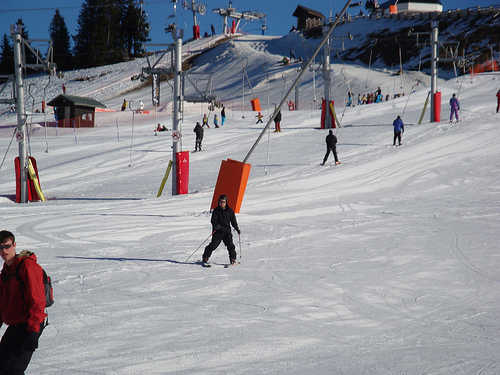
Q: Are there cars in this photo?
A: No, there are no cars.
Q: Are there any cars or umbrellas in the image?
A: No, there are no cars or umbrellas.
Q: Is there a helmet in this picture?
A: No, there are no helmets.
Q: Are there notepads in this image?
A: No, there are no notepads.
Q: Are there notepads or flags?
A: No, there are no notepads or flags.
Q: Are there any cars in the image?
A: No, there are no cars.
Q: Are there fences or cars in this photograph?
A: No, there are no cars or fences.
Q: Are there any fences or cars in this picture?
A: No, there are no fences or cars.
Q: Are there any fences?
A: No, there are no fences.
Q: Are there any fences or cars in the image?
A: No, there are no fences or cars.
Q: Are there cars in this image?
A: No, there are no cars.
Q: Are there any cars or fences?
A: No, there are no cars or fences.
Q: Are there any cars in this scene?
A: No, there are no cars.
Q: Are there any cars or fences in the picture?
A: No, there are no cars or fences.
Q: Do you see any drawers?
A: No, there are no drawers.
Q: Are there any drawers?
A: No, there are no drawers.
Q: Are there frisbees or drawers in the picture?
A: No, there are no drawers or frisbees.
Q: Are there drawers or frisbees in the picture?
A: No, there are no drawers or frisbees.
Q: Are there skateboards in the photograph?
A: No, there are no skateboards.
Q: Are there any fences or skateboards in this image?
A: No, there are no skateboards or fences.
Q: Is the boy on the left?
A: Yes, the boy is on the left of the image.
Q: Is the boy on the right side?
A: No, the boy is on the left of the image.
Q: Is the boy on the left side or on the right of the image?
A: The boy is on the left of the image.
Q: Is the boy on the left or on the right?
A: The boy is on the left of the image.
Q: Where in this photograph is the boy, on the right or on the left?
A: The boy is on the left of the image.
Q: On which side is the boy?
A: The boy is on the left of the image.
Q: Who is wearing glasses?
A: The boy is wearing glasses.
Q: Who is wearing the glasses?
A: The boy is wearing glasses.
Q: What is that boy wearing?
A: The boy is wearing glasses.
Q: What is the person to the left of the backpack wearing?
A: The boy is wearing glasses.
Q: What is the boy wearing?
A: The boy is wearing glasses.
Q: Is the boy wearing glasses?
A: Yes, the boy is wearing glasses.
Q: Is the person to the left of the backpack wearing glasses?
A: Yes, the boy is wearing glasses.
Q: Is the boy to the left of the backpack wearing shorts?
A: No, the boy is wearing glasses.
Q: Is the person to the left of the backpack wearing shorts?
A: No, the boy is wearing glasses.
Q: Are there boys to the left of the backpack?
A: Yes, there is a boy to the left of the backpack.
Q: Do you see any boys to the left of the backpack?
A: Yes, there is a boy to the left of the backpack.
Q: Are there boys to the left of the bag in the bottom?
A: Yes, there is a boy to the left of the backpack.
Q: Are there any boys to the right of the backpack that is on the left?
A: No, the boy is to the left of the backpack.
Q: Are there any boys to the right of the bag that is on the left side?
A: No, the boy is to the left of the backpack.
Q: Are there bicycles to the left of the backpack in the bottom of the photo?
A: No, there is a boy to the left of the backpack.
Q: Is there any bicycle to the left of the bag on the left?
A: No, there is a boy to the left of the backpack.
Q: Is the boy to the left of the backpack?
A: Yes, the boy is to the left of the backpack.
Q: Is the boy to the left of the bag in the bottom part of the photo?
A: Yes, the boy is to the left of the backpack.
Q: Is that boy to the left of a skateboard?
A: No, the boy is to the left of the backpack.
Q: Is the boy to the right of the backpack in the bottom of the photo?
A: No, the boy is to the left of the backpack.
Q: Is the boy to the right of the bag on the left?
A: No, the boy is to the left of the backpack.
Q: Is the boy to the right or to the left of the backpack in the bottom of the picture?
A: The boy is to the left of the backpack.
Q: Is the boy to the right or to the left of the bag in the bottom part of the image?
A: The boy is to the left of the backpack.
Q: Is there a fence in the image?
A: No, there are no fences.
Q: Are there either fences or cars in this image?
A: No, there are no fences or cars.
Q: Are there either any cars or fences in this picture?
A: No, there are no fences or cars.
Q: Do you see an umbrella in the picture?
A: No, there are no umbrellas.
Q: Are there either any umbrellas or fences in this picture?
A: No, there are no umbrellas or fences.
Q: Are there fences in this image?
A: No, there are no fences.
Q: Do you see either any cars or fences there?
A: No, there are no fences or cars.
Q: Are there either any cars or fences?
A: No, there are no fences or cars.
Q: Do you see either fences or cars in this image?
A: No, there are no fences or cars.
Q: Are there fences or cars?
A: No, there are no fences or cars.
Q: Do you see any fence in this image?
A: No, there are no fences.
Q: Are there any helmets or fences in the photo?
A: No, there are no fences or helmets.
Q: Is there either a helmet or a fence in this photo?
A: No, there are no fences or helmets.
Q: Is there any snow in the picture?
A: Yes, there is snow.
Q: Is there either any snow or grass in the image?
A: Yes, there is snow.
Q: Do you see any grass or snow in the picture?
A: Yes, there is snow.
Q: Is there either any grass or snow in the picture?
A: Yes, there is snow.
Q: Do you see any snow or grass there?
A: Yes, there is snow.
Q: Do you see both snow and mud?
A: No, there is snow but no mud.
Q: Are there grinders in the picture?
A: No, there are no grinders.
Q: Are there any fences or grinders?
A: No, there are no grinders or fences.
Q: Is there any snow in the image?
A: Yes, there is snow.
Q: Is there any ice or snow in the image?
A: Yes, there is snow.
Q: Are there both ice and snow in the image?
A: No, there is snow but no ice.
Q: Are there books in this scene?
A: No, there are no books.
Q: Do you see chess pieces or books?
A: No, there are no books or chess pieces.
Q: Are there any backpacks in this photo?
A: Yes, there is a backpack.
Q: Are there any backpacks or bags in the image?
A: Yes, there is a backpack.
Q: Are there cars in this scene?
A: No, there are no cars.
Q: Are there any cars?
A: No, there are no cars.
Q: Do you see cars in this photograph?
A: No, there are no cars.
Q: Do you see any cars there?
A: No, there are no cars.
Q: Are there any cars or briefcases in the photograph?
A: No, there are no cars or briefcases.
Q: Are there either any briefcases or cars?
A: No, there are no cars or briefcases.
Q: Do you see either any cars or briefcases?
A: No, there are no cars or briefcases.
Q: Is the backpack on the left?
A: Yes, the backpack is on the left of the image.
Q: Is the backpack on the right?
A: No, the backpack is on the left of the image.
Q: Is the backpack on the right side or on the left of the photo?
A: The backpack is on the left of the image.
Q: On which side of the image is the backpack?
A: The backpack is on the left of the image.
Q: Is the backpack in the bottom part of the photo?
A: Yes, the backpack is in the bottom of the image.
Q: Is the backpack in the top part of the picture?
A: No, the backpack is in the bottom of the image.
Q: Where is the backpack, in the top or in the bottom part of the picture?
A: The backpack is in the bottom of the image.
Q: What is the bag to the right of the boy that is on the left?
A: The bag is a backpack.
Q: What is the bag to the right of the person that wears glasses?
A: The bag is a backpack.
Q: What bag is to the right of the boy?
A: The bag is a backpack.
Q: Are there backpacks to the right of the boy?
A: Yes, there is a backpack to the right of the boy.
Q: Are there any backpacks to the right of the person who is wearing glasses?
A: Yes, there is a backpack to the right of the boy.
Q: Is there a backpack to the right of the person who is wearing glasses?
A: Yes, there is a backpack to the right of the boy.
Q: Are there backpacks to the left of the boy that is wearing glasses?
A: No, the backpack is to the right of the boy.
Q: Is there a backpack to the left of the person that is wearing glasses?
A: No, the backpack is to the right of the boy.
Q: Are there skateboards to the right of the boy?
A: No, there is a backpack to the right of the boy.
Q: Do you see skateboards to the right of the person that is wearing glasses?
A: No, there is a backpack to the right of the boy.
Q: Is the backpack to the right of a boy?
A: Yes, the backpack is to the right of a boy.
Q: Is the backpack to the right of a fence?
A: No, the backpack is to the right of a boy.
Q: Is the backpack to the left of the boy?
A: No, the backpack is to the right of the boy.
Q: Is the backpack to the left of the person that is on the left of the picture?
A: No, the backpack is to the right of the boy.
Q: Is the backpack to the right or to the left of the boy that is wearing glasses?
A: The backpack is to the right of the boy.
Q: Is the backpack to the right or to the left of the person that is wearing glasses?
A: The backpack is to the right of the boy.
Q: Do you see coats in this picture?
A: Yes, there is a coat.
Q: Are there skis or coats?
A: Yes, there is a coat.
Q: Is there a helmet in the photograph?
A: No, there are no helmets.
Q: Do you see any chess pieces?
A: No, there are no chess pieces.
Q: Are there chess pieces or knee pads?
A: No, there are no chess pieces or knee pads.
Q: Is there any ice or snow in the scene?
A: Yes, there is snow.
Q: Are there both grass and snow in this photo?
A: No, there is snow but no grass.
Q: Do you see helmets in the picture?
A: No, there are no helmets.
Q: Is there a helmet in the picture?
A: No, there are no helmets.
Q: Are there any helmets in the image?
A: No, there are no helmets.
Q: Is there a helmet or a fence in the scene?
A: No, there are no helmets or fences.